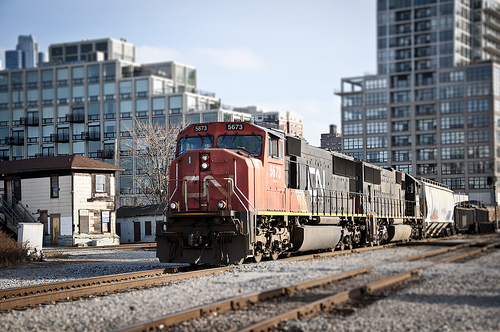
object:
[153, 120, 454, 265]
train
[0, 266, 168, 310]
tracks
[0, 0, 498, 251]
building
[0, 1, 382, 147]
sky